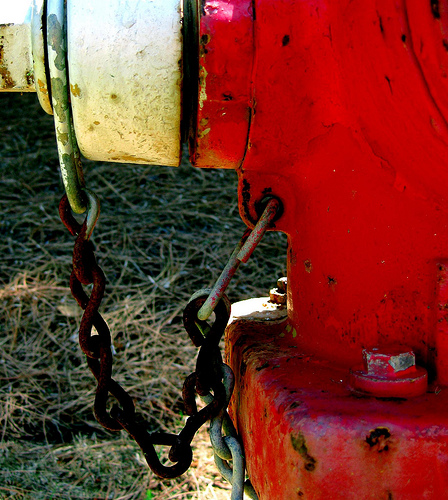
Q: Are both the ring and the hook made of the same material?
A: Yes, both the ring and the hook are made of metal.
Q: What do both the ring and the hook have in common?
A: The material, both the ring and the hook are metallic.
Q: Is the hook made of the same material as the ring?
A: Yes, both the hook and the ring are made of metal.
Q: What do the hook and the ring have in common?
A: The material, both the hook and the ring are metallic.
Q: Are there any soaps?
A: No, there are no soaps.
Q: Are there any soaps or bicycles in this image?
A: No, there are no soaps or bicycles.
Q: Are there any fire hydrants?
A: Yes, there is a fire hydrant.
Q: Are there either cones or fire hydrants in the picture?
A: Yes, there is a fire hydrant.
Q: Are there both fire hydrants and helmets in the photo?
A: No, there is a fire hydrant but no helmets.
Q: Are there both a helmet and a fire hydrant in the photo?
A: No, there is a fire hydrant but no helmets.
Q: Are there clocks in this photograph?
A: No, there are no clocks.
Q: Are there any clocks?
A: No, there are no clocks.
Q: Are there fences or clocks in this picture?
A: No, there are no clocks or fences.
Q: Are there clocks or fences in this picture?
A: No, there are no clocks or fences.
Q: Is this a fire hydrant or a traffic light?
A: This is a fire hydrant.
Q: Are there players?
A: No, there are no players.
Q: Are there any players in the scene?
A: No, there are no players.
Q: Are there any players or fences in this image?
A: No, there are no players or fences.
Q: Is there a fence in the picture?
A: No, there are no fences.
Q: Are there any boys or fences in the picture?
A: No, there are no fences or boys.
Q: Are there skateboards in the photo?
A: No, there are no skateboards.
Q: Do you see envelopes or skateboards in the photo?
A: No, there are no skateboards or envelopes.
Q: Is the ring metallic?
A: Yes, the ring is metallic.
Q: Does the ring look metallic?
A: Yes, the ring is metallic.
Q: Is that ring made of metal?
A: Yes, the ring is made of metal.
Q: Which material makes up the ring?
A: The ring is made of metal.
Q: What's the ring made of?
A: The ring is made of metal.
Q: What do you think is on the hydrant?
A: The ring is on the hydrant.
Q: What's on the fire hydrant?
A: The ring is on the hydrant.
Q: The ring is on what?
A: The ring is on the fire hydrant.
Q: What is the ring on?
A: The ring is on the fire hydrant.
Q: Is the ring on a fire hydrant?
A: Yes, the ring is on a fire hydrant.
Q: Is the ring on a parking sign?
A: No, the ring is on a fire hydrant.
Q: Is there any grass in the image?
A: Yes, there is grass.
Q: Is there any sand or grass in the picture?
A: Yes, there is grass.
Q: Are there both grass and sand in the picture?
A: No, there is grass but no sand.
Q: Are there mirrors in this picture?
A: No, there are no mirrors.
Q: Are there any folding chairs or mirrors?
A: No, there are no mirrors or folding chairs.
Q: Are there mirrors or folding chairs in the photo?
A: No, there are no mirrors or folding chairs.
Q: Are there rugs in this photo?
A: No, there are no rugs.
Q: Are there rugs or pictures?
A: No, there are no rugs or pictures.